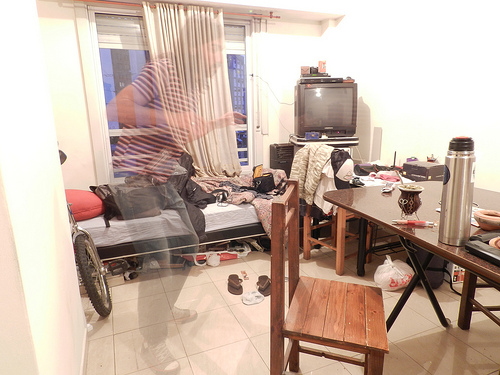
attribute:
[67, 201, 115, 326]
bicycle — small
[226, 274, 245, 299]
brown flip-flop — pair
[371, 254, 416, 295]
plastic bag — white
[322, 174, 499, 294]
dark table — holding, brown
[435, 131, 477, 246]
black thermos — silver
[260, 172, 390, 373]
wooden chair — brown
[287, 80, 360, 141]
television near wall — black, blue, gray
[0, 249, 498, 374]
floor of tiles — white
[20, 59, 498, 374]
room — cluttered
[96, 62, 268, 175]
window — large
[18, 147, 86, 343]
wall — white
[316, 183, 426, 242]
table — wooden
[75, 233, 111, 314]
wheel — black